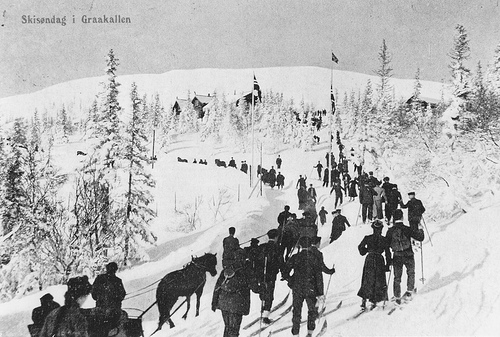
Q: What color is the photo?
A: Black and white.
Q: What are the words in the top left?
A: Skisondag i Graakallen.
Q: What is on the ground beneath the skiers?
A: Snow.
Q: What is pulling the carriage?
A: Horse.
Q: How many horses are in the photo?
A: 1.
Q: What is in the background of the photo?
A: Mountain.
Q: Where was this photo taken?
A: Ski slope.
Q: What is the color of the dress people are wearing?
A: Black.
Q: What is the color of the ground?
A: White.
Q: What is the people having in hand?
A: Ski poles.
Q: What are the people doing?
A: Climbing the hill.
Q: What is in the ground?
A: Snow.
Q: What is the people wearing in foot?
A: Ski board.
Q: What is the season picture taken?
A: Winter.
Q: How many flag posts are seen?
A: 2.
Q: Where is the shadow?
A: In the snow.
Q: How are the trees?
A: Covered with snow.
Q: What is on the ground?
A: Snow.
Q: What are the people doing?
A: Skiing.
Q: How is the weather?
A: Snowy.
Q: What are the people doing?
A: Traveling through snow.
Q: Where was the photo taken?
A: Snowy mountains.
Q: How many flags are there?
A: 3.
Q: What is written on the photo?
A: Skisondag i Graakallen.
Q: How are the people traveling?
A: By skis.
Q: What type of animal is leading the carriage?
A: Horse.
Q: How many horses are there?
A: 1.